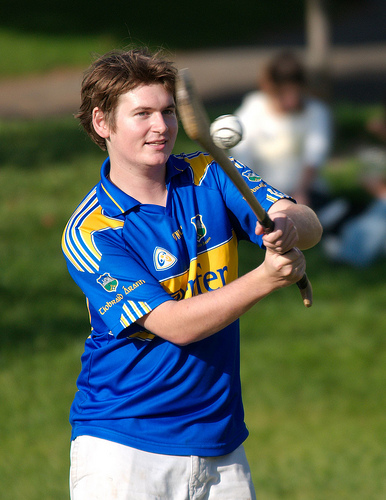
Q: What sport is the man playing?
A: Baseball.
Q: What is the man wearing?
A: Jersey.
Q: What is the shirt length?
A: Short.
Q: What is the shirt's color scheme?
A: Blue yellow and white.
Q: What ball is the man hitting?
A: Baseball.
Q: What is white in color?
A: Shorts.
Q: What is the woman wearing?
A: Shirt.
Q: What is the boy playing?
A: Cricket.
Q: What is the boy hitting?
A: Ball.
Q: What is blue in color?
A: Shirt.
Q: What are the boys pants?
A: White.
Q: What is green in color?
A: Grass.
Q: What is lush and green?
A: Grass.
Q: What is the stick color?
A: The stick is brown.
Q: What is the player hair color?
A: The player hair is brown.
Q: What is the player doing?
A: He is swinging.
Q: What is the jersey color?
A: The jersey color is yellow and blue.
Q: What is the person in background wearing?
A: The person in the background is wearing white.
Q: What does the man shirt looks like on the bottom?
A: The shirt is wrinkles.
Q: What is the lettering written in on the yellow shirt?
A: The writing is in blue letters.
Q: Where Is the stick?
A: In the man's hands.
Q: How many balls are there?
A: One.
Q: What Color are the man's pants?
A: White.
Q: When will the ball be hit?
A: Right now.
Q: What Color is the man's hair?
A: Brown.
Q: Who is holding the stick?
A: The man.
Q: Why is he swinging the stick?
A: To hit the ball.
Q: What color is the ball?
A: White.